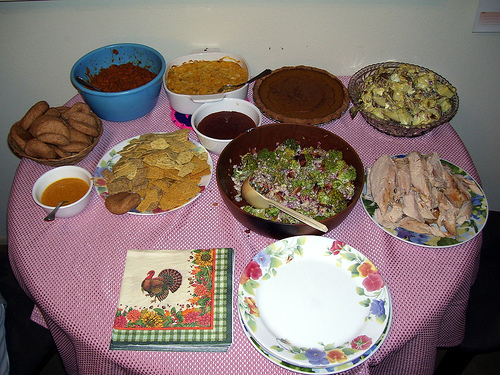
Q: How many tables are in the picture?
A: One.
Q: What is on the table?
A: Food.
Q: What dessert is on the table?
A: A pie.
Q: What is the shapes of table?
A: Round.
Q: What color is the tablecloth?
A: Red and white.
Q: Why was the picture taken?
A: To capture the food.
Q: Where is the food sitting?
A: On a table.